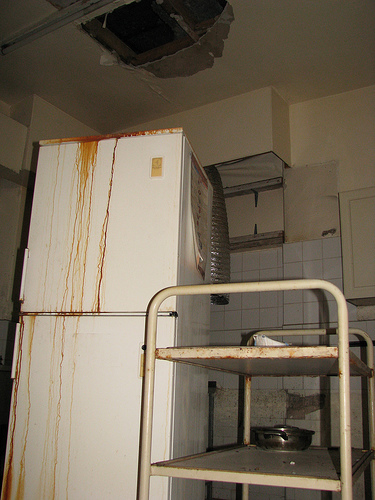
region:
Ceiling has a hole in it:
[46, 3, 234, 76]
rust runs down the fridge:
[3, 125, 184, 498]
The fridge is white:
[2, 126, 212, 498]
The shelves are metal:
[135, 281, 373, 499]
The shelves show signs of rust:
[136, 282, 370, 497]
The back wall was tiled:
[194, 233, 374, 395]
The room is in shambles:
[0, 0, 374, 498]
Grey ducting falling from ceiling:
[202, 161, 231, 308]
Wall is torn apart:
[204, 383, 373, 499]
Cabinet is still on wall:
[331, 182, 373, 306]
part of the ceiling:
[316, 29, 354, 72]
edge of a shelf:
[229, 468, 262, 484]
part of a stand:
[136, 437, 153, 470]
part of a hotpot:
[268, 431, 289, 448]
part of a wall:
[312, 253, 330, 273]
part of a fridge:
[99, 422, 129, 456]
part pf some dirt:
[84, 268, 107, 306]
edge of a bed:
[255, 267, 322, 300]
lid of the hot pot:
[278, 424, 294, 431]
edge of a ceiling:
[165, 38, 191, 62]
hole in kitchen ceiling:
[84, 2, 222, 78]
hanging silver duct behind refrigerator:
[199, 162, 238, 301]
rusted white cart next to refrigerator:
[128, 277, 368, 490]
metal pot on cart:
[242, 415, 322, 454]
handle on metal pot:
[257, 428, 289, 445]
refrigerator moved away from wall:
[19, 129, 215, 469]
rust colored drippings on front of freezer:
[50, 131, 126, 271]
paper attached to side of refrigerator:
[183, 148, 218, 281]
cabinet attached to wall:
[314, 182, 370, 315]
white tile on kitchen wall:
[260, 244, 325, 276]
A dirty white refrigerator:
[16, 117, 178, 497]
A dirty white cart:
[123, 284, 349, 481]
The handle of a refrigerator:
[7, 312, 32, 399]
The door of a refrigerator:
[8, 314, 183, 441]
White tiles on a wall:
[280, 216, 325, 268]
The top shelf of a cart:
[145, 291, 364, 378]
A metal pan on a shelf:
[227, 412, 324, 461]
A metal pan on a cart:
[116, 379, 356, 494]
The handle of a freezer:
[10, 244, 59, 309]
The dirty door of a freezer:
[19, 135, 188, 321]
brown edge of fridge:
[45, 118, 187, 141]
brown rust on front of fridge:
[57, 205, 137, 256]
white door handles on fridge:
[13, 246, 41, 375]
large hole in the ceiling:
[89, 17, 269, 102]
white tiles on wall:
[261, 252, 318, 297]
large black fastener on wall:
[303, 222, 354, 250]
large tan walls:
[298, 92, 356, 132]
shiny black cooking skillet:
[250, 415, 331, 461]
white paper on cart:
[244, 326, 286, 350]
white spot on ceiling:
[85, 43, 130, 70]